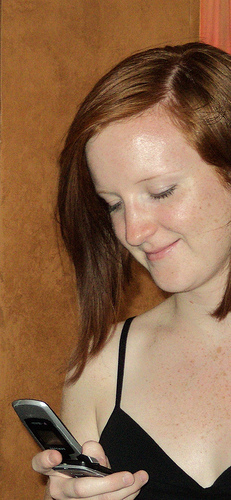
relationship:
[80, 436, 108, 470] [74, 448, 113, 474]
thumb over phone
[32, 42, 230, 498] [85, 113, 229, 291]
girl has face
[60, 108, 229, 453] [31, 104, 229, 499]
freckles on skin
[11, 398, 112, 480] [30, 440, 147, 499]
cell phone in hand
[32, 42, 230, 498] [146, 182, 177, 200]
girl has eye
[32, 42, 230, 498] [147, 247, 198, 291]
girl has chin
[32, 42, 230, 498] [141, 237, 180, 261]
girl has lips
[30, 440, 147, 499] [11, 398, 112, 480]
hand holding cell phone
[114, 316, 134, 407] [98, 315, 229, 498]
strap on top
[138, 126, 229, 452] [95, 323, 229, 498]
freckles on chest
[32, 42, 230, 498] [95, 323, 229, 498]
girl has chest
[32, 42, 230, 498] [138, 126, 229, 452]
girl has freckles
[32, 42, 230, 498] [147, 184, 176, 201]
girl has eyelashes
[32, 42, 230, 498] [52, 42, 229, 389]
girl has hair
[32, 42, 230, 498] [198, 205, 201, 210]
girl has beauty mark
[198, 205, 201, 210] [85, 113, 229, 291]
beauty mark on face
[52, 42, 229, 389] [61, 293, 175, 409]
hair gently touching shoulder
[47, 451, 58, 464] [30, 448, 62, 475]
fingernail growing on finger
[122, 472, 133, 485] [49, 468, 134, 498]
fingernail growing on finger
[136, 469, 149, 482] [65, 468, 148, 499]
fingernail growing on finger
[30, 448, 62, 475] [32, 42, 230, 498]
finger belonging to girl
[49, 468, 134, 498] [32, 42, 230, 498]
finger belonging to girl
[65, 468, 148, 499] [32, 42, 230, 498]
finger belonging to girl